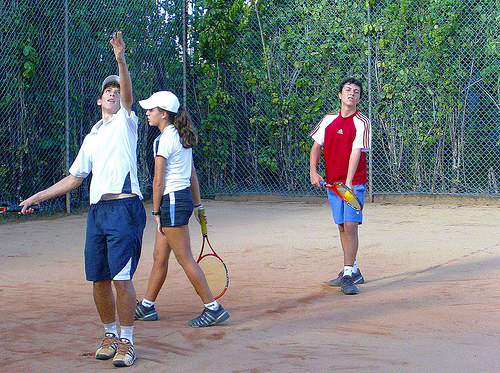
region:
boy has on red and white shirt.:
[310, 108, 372, 195]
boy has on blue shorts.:
[322, 180, 364, 227]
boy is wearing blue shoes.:
[325, 268, 365, 297]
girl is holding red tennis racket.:
[188, 200, 230, 302]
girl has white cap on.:
[137, 88, 179, 115]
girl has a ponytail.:
[174, 100, 199, 150]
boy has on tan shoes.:
[96, 330, 136, 365]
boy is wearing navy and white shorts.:
[81, 197, 143, 282]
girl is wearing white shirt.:
[154, 125, 197, 195]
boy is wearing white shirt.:
[73, 111, 141, 198]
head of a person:
[325, 72, 365, 102]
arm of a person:
[299, 119, 337, 189]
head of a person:
[143, 82, 198, 130]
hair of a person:
[180, 123, 191, 138]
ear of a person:
[158, 110, 180, 122]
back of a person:
[174, 143, 196, 214]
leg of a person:
[159, 195, 223, 297]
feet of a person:
[125, 294, 165, 319]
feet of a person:
[177, 303, 256, 345]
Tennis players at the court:
[41, 42, 414, 341]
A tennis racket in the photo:
[190, 209, 240, 310]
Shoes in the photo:
[87, 324, 147, 368]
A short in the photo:
[160, 189, 193, 229]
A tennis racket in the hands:
[333, 178, 362, 211]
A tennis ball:
[339, 186, 364, 211]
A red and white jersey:
[312, 102, 392, 179]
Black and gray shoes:
[140, 294, 232, 326]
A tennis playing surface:
[253, 244, 421, 369]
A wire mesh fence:
[205, 47, 289, 139]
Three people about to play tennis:
[23, 22, 399, 369]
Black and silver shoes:
[124, 295, 231, 325]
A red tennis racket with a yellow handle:
[189, 200, 233, 311]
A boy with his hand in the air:
[9, 17, 156, 368]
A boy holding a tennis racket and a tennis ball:
[314, 70, 380, 287]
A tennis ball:
[336, 182, 358, 202]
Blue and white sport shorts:
[81, 192, 143, 279]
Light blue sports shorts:
[323, 180, 365, 225]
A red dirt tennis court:
[1, 195, 495, 372]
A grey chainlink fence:
[1, 2, 497, 209]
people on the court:
[42, 58, 379, 350]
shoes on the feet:
[323, 273, 359, 296]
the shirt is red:
[332, 150, 343, 161]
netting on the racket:
[205, 265, 220, 280]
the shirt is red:
[105, 145, 130, 178]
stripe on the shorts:
[167, 192, 179, 230]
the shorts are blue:
[109, 215, 127, 247]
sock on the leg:
[117, 326, 134, 338]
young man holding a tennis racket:
[308, 77, 373, 297]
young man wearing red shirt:
[307, 76, 374, 295]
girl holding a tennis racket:
[133, 90, 230, 327]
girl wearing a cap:
[130, 91, 231, 328]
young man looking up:
[18, 28, 144, 366]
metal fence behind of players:
[0, 0, 497, 225]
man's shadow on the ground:
[353, 256, 498, 291]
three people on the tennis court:
[17, 29, 372, 366]